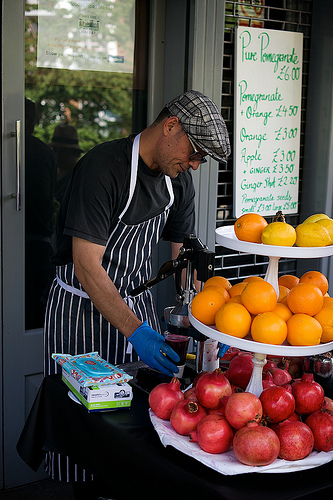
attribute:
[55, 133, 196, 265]
shirt — black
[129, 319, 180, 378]
glove — blue, plastic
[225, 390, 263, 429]
pomegranate — red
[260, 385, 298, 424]
pomegranate — red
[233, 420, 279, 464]
pomegranate — red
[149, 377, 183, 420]
pomegranate — red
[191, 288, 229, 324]
orange — middle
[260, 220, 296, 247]
lemon — one, top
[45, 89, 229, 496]
man — working, making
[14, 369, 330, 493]
tablecloth — black, vinyl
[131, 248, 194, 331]
handle — silver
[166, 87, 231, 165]
hat — patterned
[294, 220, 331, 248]
lemon — yellow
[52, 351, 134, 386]
wipe — moist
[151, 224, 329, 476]
stand — white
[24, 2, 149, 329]
door — glass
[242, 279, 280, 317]
orange — bright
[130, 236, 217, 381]
juicer — portable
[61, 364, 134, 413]
wipes — paper, boxed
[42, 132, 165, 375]
apron — black, striped, white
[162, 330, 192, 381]
juice — purple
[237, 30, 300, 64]
letters — green